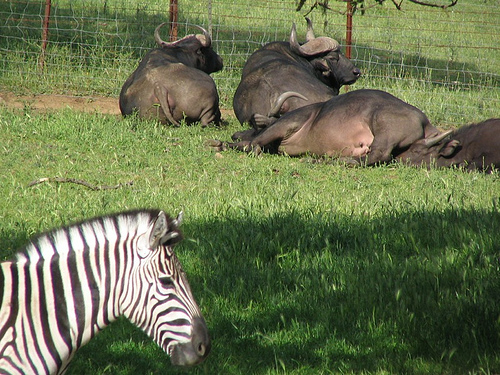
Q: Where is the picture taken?
A: A zoo.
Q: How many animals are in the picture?
A: 5.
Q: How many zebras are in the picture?
A: One.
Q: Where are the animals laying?
A: On the grass.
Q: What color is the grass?
A: Green.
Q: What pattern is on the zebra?
A: Stripes.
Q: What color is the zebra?
A: Black & white.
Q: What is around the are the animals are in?
A: A fence.